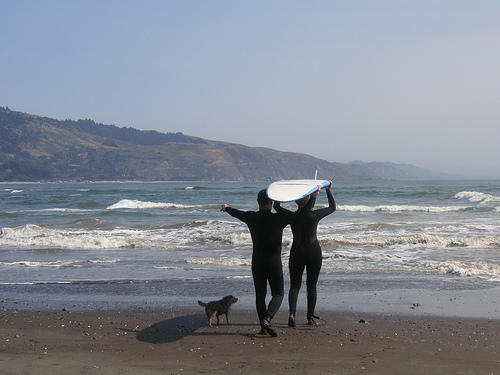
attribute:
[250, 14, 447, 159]
clouds — white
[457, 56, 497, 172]
clouds — white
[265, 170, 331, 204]
surfboard — white, blue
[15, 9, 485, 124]
sky — clear, blue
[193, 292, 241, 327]
dog — small, brown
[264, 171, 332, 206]
board — carried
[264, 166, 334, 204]
surfboard — blue, white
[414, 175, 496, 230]
wave — large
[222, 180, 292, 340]
surfer — carrying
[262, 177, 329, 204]
surfboard — white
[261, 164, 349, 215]
surfboard — carried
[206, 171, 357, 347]
people — wearing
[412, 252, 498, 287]
wave — smal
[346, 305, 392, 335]
brown rock — strewn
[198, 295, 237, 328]
dog — small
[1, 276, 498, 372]
beach — wet, sandy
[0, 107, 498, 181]
hills — Brown , green 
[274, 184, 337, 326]
person — carrying, white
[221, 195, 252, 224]
arm — stretched out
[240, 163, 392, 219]
surfboard — blue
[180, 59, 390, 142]
clouds — white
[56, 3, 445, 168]
sky — blue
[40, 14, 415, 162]
sky — blue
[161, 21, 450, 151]
sky — blue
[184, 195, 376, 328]
people — approaching